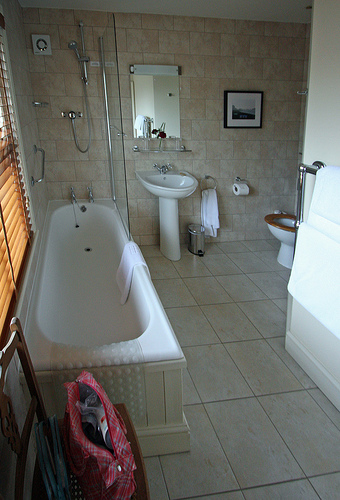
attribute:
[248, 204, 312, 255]
toilet — wooden 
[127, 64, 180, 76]
light — off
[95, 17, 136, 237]
partition — glass 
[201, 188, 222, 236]
towel — white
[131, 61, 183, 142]
bathroom mirror — frameless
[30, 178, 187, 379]
bathtub — rectangular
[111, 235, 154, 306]
mat — white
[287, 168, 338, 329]
towels — white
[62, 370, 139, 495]
bag — white, pink 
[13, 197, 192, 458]
basin — oblong, tub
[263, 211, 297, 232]
seat — toilet, brown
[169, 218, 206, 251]
trashcan — silver 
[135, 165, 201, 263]
sink — white 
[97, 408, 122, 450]
tube — white 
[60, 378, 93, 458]
bag — unzipped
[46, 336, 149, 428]
mat — knobby, bathtub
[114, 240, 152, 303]
towel — white